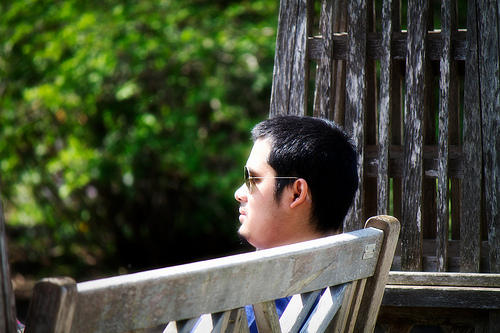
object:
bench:
[23, 214, 399, 332]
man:
[233, 110, 363, 332]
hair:
[247, 113, 357, 230]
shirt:
[241, 281, 330, 332]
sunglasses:
[242, 165, 299, 194]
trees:
[1, 0, 266, 274]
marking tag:
[361, 244, 377, 261]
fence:
[265, 1, 500, 308]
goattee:
[235, 228, 251, 242]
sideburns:
[271, 182, 291, 208]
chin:
[237, 223, 256, 248]